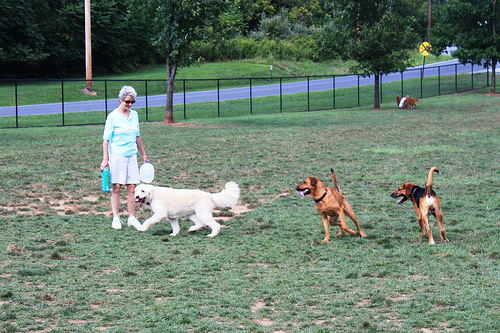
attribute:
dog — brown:
[391, 165, 457, 242]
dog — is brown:
[295, 163, 372, 246]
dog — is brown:
[120, 177, 244, 247]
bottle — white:
[139, 157, 155, 182]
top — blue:
[143, 160, 146, 161]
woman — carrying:
[98, 83, 148, 230]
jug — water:
[138, 158, 155, 182]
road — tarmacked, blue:
[0, 55, 498, 115]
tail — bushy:
[210, 179, 242, 209]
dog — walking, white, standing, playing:
[132, 179, 241, 238]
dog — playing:
[127, 169, 243, 235]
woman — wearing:
[97, 81, 154, 233]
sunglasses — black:
[119, 98, 136, 106]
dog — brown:
[393, 167, 466, 241]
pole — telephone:
[85, 0, 92, 93]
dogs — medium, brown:
[288, 166, 372, 243]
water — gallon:
[135, 157, 158, 193]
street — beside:
[0, 56, 497, 118]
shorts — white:
[104, 152, 142, 189]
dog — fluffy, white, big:
[123, 172, 243, 239]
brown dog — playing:
[390, 162, 452, 247]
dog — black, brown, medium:
[371, 153, 488, 248]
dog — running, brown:
[259, 136, 381, 268]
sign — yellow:
[417, 38, 435, 59]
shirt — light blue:
[63, 67, 160, 160]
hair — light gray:
[122, 87, 134, 92]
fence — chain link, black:
[2, 49, 498, 129]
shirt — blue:
[92, 107, 160, 162]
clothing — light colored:
[101, 110, 144, 186]